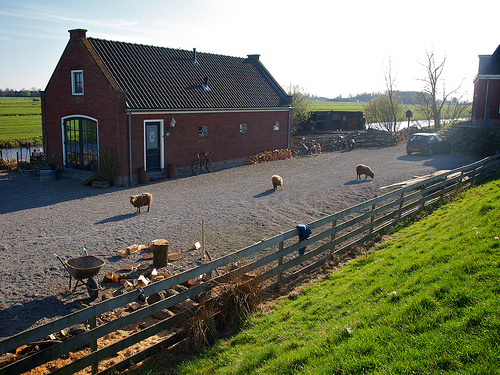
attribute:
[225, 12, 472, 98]
clouds — white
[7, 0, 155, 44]
sky — blue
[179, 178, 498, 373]
grass — green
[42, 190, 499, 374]
fence — wood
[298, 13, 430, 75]
clouds — white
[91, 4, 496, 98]
sky — blue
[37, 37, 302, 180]
barn — brick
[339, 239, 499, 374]
grass — green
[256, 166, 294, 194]
sheep — brown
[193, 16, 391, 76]
clouds — white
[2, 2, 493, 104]
sky — blue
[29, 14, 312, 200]
barn — red, brick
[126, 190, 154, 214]
sheep — brown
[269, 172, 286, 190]
sheep — brown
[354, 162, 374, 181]
sheep — brown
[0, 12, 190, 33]
cloud — white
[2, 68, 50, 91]
cloud — white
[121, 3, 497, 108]
cloud — white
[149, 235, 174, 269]
logs — chopped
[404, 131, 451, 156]
car — parked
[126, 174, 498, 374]
grass — green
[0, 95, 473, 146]
grass — green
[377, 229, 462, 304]
grass — green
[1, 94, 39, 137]
grass — green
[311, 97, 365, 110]
grass — green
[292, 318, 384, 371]
part — Small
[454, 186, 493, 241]
part — Small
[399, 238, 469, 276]
part — Small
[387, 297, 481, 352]
part — Small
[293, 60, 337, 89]
cloud — white, blue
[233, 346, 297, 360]
part — Small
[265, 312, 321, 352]
part — Small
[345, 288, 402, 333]
part — small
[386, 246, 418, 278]
part — small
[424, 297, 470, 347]
part — Small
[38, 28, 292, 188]
house — modern